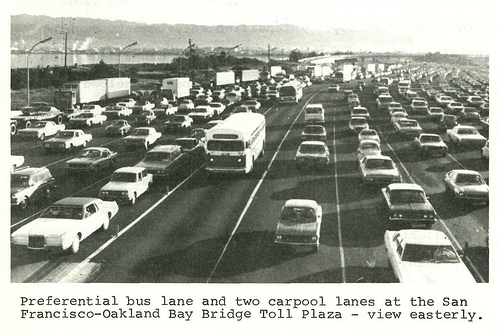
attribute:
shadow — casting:
[134, 231, 272, 275]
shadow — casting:
[271, 178, 372, 202]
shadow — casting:
[319, 203, 382, 247]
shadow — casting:
[255, 159, 294, 177]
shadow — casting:
[385, 141, 418, 166]